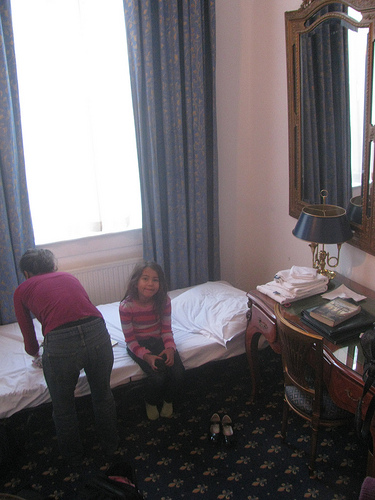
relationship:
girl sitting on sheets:
[117, 256, 185, 427] [2, 273, 264, 410]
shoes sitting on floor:
[203, 410, 238, 450] [2, 332, 375, 493]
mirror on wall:
[281, 0, 374, 258] [209, 1, 373, 298]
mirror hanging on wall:
[281, 0, 374, 258] [209, 1, 373, 298]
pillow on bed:
[167, 273, 263, 350] [4, 274, 272, 427]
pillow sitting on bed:
[167, 273, 263, 350] [4, 274, 272, 427]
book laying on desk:
[308, 294, 362, 327] [237, 267, 374, 488]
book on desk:
[308, 294, 362, 327] [237, 267, 374, 488]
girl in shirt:
[117, 256, 185, 427] [117, 295, 175, 359]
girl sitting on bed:
[117, 256, 185, 427] [4, 274, 272, 427]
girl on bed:
[117, 256, 185, 427] [4, 274, 272, 427]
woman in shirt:
[12, 247, 123, 477] [12, 266, 105, 357]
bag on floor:
[76, 457, 147, 498] [2, 332, 375, 493]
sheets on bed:
[2, 273, 264, 410] [4, 274, 272, 427]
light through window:
[10, 1, 148, 245] [8, 0, 157, 274]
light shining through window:
[10, 1, 148, 245] [8, 0, 157, 274]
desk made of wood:
[237, 267, 374, 488] [244, 269, 373, 470]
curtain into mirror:
[2, 0, 47, 323] [281, 0, 374, 258]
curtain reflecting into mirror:
[2, 0, 47, 323] [281, 0, 374, 258]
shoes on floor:
[203, 410, 238, 450] [2, 332, 375, 493]